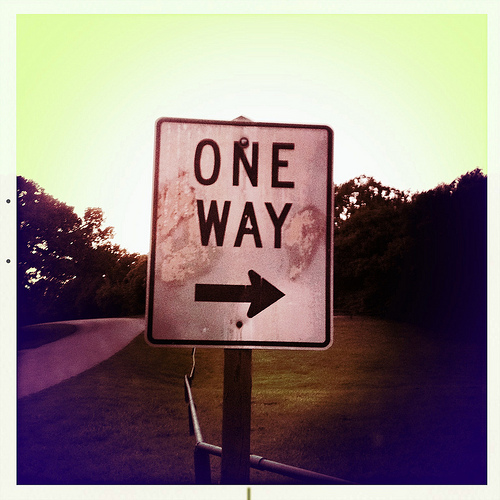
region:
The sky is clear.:
[22, 17, 459, 213]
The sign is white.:
[147, 120, 332, 343]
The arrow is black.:
[177, 277, 297, 308]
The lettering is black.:
[180, 125, 298, 252]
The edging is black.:
[140, 115, 333, 352]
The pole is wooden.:
[218, 348, 262, 490]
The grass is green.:
[42, 332, 465, 485]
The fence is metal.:
[170, 349, 292, 499]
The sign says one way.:
[140, 97, 341, 353]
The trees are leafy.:
[19, 177, 499, 321]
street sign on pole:
[148, 112, 339, 349]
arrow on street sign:
[188, 267, 277, 322]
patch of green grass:
[125, 402, 132, 410]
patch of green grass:
[302, 416, 319, 441]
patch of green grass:
[353, 428, 365, 445]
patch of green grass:
[133, 455, 153, 477]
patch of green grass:
[288, 357, 307, 369]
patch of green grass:
[367, 415, 382, 431]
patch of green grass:
[74, 440, 88, 460]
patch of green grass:
[164, 410, 175, 425]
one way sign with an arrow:
[135, 79, 375, 371]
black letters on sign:
[175, 128, 307, 270]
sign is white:
[160, 138, 325, 381]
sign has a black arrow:
[168, 256, 311, 337]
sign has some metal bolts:
[224, 312, 262, 344]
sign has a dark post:
[205, 325, 285, 499]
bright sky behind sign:
[35, 20, 460, 223]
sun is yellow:
[85, 72, 215, 284]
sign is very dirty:
[161, 172, 331, 299]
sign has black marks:
[150, 174, 354, 318]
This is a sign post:
[131, 107, 336, 497]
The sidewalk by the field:
[20, 321, 144, 393]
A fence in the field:
[172, 345, 345, 486]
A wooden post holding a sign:
[221, 343, 250, 486]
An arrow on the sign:
[191, 269, 285, 317]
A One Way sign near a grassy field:
[156, 115, 335, 485]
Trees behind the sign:
[11, 168, 483, 322]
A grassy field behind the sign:
[22, 327, 485, 484]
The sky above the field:
[16, 12, 488, 190]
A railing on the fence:
[178, 345, 335, 482]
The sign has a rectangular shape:
[154, 123, 329, 346]